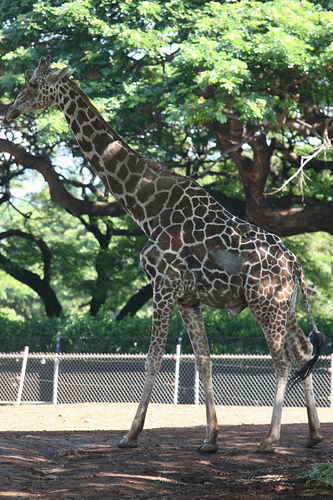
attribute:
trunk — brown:
[0, 230, 63, 318]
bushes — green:
[0, 315, 331, 350]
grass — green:
[298, 460, 331, 488]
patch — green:
[291, 453, 329, 486]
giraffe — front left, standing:
[5, 54, 324, 455]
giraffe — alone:
[20, 71, 305, 489]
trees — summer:
[28, 7, 316, 218]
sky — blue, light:
[23, 178, 44, 190]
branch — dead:
[235, 112, 332, 228]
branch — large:
[0, 111, 332, 239]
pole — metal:
[12, 344, 29, 405]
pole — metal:
[50, 333, 63, 404]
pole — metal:
[172, 344, 181, 403]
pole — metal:
[193, 352, 198, 402]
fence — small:
[30, 358, 92, 382]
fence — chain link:
[26, 321, 331, 441]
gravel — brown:
[0, 403, 330, 422]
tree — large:
[1, 227, 68, 341]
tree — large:
[66, 153, 161, 315]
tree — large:
[113, 280, 154, 323]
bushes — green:
[1, 312, 332, 356]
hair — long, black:
[282, 356, 312, 401]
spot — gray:
[207, 245, 248, 280]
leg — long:
[176, 309, 224, 457]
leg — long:
[113, 301, 172, 450]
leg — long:
[250, 309, 295, 454]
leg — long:
[285, 321, 322, 450]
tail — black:
[282, 263, 323, 399]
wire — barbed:
[4, 331, 323, 347]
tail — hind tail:
[284, 249, 322, 395]